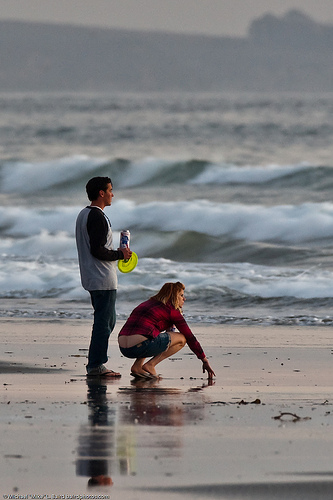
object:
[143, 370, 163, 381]
flipflops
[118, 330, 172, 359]
shorts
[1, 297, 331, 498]
shore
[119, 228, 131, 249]
beverage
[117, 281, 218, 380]
woman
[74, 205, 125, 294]
shirt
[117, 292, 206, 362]
shirt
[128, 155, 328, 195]
waves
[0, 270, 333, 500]
ground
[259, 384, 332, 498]
sand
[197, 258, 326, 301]
foam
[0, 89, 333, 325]
ocean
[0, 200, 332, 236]
waves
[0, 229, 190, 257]
waves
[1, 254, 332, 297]
waves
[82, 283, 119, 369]
jeans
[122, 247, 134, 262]
hand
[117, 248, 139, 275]
frisbee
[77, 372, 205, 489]
reflection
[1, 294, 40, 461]
sand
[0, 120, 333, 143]
wave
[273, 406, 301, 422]
debris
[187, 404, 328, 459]
sand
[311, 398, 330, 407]
debris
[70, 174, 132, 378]
man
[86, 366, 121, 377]
sandals